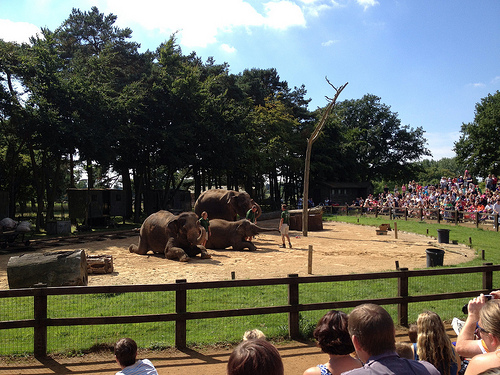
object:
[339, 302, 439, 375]
man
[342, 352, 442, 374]
shirt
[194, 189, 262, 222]
elephant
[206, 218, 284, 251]
elephant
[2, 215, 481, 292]
dirt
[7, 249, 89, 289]
log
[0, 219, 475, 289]
dirt area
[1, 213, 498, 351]
grass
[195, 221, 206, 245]
trunk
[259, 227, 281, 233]
trunk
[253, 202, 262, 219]
trunk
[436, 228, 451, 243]
black bin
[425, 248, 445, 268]
black bin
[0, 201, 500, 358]
enclosure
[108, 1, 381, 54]
clouds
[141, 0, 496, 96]
sky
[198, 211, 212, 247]
people elephants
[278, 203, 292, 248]
person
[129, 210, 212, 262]
elephant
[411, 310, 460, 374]
woman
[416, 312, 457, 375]
hair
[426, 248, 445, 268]
trash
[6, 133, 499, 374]
viewers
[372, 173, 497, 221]
crowd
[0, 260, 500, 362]
fence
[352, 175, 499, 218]
people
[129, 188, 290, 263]
show